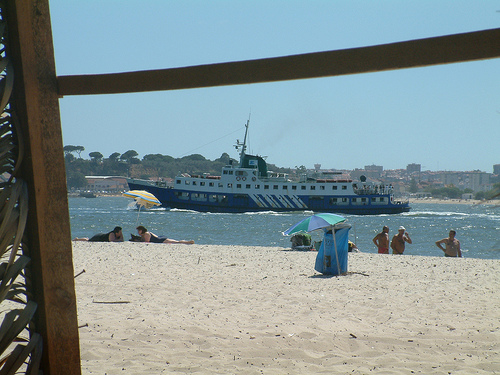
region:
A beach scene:
[29, 28, 477, 357]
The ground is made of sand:
[146, 270, 280, 362]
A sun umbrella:
[278, 206, 351, 243]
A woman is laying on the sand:
[129, 220, 200, 252]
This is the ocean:
[191, 212, 263, 237]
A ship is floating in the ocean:
[118, 114, 417, 214]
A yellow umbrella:
[119, 185, 167, 210]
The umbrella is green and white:
[280, 211, 351, 242]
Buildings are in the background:
[381, 157, 497, 199]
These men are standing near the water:
[366, 221, 468, 257]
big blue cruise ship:
[119, 96, 435, 219]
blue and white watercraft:
[111, 103, 448, 230]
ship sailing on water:
[122, 106, 420, 221]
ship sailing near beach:
[107, 101, 441, 221]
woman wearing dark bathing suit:
[127, 219, 209, 249]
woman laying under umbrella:
[129, 216, 210, 250]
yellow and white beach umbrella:
[114, 182, 165, 239]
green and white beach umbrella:
[286, 203, 350, 279]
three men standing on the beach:
[372, 217, 471, 267]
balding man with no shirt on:
[370, 218, 392, 258]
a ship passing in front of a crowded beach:
[6, 5, 488, 327]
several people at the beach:
[370, 220, 477, 281]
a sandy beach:
[84, 212, 491, 345]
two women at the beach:
[78, 214, 213, 265]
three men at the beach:
[372, 210, 471, 283]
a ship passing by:
[116, 124, 463, 226]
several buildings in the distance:
[307, 143, 494, 218]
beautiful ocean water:
[106, 192, 474, 249]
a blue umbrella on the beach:
[281, 195, 370, 287]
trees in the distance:
[61, 140, 152, 172]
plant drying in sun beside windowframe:
[0, 0, 45, 374]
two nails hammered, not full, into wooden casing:
[71, 265, 91, 342]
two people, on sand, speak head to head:
[72, 222, 199, 248]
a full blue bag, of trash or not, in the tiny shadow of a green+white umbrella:
[272, 208, 372, 285]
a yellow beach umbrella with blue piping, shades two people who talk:
[115, 186, 165, 251]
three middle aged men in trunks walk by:
[367, 220, 467, 264]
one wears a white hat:
[396, 223, 405, 235]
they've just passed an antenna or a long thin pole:
[351, 218, 362, 255]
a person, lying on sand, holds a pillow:
[127, 228, 143, 244]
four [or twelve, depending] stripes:
[243, 190, 312, 212]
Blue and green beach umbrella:
[252, 196, 362, 241]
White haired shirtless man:
[389, 220, 416, 257]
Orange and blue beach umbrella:
[112, 178, 166, 217]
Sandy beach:
[60, 247, 468, 372]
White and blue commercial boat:
[120, 117, 435, 215]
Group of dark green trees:
[69, 140, 238, 179]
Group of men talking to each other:
[372, 220, 469, 260]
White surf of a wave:
[412, 204, 489, 220]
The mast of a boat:
[235, 99, 264, 175]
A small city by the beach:
[357, 157, 489, 197]